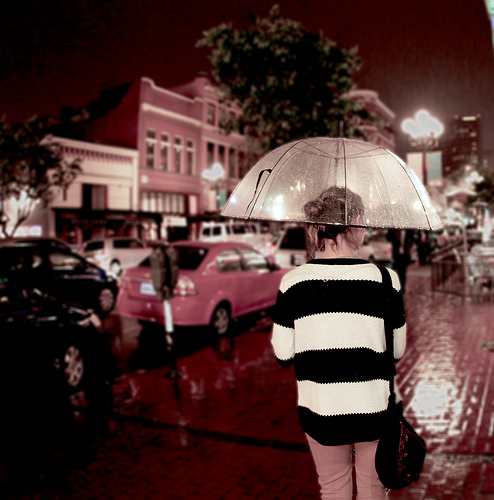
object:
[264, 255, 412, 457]
sweater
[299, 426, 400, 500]
pants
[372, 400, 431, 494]
purse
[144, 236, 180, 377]
meter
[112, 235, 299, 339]
car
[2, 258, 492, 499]
sidewalk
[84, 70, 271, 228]
building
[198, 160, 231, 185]
bulbs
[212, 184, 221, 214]
pole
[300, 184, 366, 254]
hair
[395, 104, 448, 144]
lights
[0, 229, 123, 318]
van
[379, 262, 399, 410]
strap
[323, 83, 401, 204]
buildings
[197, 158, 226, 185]
top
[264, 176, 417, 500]
woman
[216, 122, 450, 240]
umbrella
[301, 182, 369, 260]
head